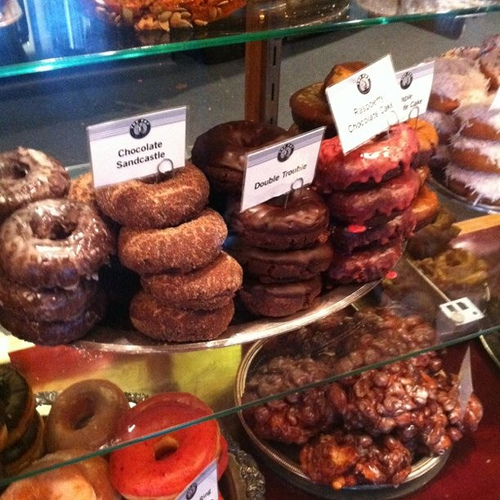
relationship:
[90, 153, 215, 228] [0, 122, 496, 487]
pastry on shelf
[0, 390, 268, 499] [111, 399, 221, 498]
platter with doughnuts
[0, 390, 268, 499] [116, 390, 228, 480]
platter with pastry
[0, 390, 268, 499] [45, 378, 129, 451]
platter with doughnuts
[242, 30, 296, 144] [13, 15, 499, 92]
pole with racks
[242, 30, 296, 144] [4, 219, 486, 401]
pole with shelf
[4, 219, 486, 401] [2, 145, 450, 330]
shelf for pastries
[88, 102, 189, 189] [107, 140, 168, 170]
sandcastle sign with pastry name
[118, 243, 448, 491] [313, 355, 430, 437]
container with pastries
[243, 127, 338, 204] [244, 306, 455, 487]
tag in pastry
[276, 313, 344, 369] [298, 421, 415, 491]
donut in donut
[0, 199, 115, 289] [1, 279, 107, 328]
donut next to donut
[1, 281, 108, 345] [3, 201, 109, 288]
donut next to donut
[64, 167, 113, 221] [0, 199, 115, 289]
donut next to donut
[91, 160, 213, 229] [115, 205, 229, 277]
donut next to donut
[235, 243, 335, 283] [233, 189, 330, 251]
donut next to donut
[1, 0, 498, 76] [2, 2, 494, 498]
glass shelf on top of bakery case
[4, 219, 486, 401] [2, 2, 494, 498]
shelf of bakery case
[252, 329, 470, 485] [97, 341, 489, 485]
apple fritters on bottom shelf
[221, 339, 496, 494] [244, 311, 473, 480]
metal holding apple fritters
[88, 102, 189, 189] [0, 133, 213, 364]
sandcastle sign for chocolate sandcastle pastries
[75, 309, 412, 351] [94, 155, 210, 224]
plate holding variety of pastries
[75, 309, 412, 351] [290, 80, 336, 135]
plate holding variety of pastries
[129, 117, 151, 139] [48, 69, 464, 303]
black design on sign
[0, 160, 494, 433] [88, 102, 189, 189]
doughnut name on sandcastle sign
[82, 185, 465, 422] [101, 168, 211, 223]
pile of brown pastries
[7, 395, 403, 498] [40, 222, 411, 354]
row of doughnuts on platter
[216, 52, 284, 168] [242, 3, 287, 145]
brown metal shelf pole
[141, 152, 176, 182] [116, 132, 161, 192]
clip holding sign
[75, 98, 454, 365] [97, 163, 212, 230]
stack of glazed doughnuts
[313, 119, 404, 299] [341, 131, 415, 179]
donuts covered in pink glaze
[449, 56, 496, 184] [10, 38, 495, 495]
shredded coconut on doughnut